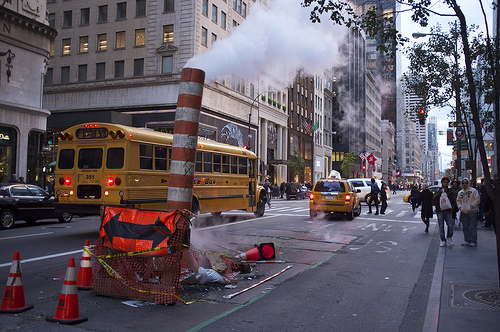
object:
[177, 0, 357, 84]
steam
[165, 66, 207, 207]
cylinder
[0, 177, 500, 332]
ground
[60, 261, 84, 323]
cone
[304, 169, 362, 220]
car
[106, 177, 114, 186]
brake light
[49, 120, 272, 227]
bus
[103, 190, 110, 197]
light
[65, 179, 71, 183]
light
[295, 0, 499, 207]
tree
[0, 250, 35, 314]
cones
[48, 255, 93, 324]
cone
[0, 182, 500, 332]
road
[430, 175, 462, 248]
man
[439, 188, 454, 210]
bag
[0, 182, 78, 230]
car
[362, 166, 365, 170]
light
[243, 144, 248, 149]
light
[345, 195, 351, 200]
light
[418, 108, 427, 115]
light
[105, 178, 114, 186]
light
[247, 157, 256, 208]
doors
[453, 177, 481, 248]
people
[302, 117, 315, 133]
flag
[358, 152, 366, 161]
flag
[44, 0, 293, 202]
building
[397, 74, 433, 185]
building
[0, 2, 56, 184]
building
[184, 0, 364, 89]
smoke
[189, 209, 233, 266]
smoke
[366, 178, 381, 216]
pedestrians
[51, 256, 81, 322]
stripes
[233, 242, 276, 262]
traffic cones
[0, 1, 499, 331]
city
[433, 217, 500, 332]
sidewalk